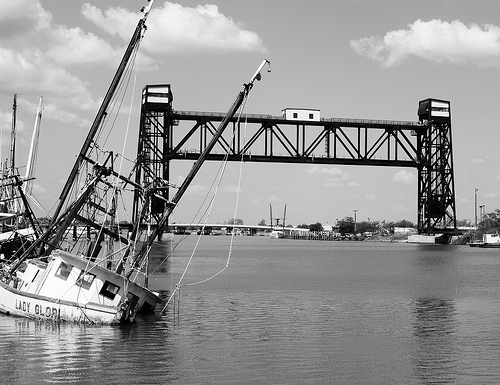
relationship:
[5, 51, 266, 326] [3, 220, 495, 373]
ship on water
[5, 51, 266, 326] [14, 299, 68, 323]
ship named lady glori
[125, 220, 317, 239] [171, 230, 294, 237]
pier for boats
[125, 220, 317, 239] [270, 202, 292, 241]
pier has crane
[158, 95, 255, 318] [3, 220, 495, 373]
ropes in water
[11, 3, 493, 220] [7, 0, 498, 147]
sky has clouds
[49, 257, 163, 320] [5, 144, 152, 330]
windows on boats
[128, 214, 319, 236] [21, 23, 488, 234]
bridge in background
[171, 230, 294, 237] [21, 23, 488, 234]
boats in background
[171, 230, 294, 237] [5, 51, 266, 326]
boats behind ship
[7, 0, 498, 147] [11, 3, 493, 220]
clouds in sky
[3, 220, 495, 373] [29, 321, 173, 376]
water has ripples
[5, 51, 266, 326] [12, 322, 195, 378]
ship cast shadow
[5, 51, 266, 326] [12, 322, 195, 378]
ship has shadow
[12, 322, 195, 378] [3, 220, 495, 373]
shadow on water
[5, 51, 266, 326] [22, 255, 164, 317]
ship has front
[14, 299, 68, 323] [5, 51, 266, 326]
lady glori on ship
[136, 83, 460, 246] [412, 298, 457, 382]
bridge cast shadow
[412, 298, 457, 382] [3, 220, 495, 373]
shadow on water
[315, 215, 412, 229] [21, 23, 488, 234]
trees in background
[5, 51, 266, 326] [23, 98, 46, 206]
ship has sail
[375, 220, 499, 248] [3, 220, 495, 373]
bank of water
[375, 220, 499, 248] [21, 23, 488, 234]
bank in background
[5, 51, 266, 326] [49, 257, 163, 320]
ship has windows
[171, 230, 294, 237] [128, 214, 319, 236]
boats under bridge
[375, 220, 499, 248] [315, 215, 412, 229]
bank has trees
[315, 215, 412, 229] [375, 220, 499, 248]
trees on bank